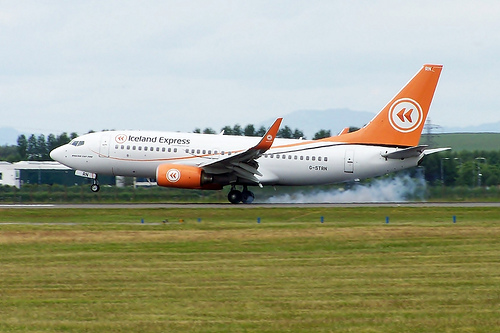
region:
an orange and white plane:
[51, 61, 448, 208]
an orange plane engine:
[155, 164, 211, 190]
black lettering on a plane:
[127, 132, 191, 146]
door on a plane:
[99, 134, 109, 157]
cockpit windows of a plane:
[67, 138, 84, 145]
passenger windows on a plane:
[111, 143, 330, 164]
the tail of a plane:
[360, 62, 442, 145]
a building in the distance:
[1, 155, 117, 192]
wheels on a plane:
[225, 188, 252, 203]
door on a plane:
[342, 146, 354, 175]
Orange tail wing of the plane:
[310, 64, 455, 148]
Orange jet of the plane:
[152, 164, 199, 186]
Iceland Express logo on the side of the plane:
[112, 130, 192, 147]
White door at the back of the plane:
[340, 149, 355, 175]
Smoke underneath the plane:
[260, 170, 426, 210]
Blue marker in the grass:
[448, 209, 464, 224]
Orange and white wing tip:
[258, 109, 285, 153]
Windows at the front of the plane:
[65, 139, 89, 147]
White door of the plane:
[97, 133, 111, 159]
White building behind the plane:
[0, 155, 138, 187]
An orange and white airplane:
[32, 52, 467, 204]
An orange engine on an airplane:
[146, 156, 214, 193]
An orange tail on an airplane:
[360, 48, 439, 150]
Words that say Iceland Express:
[124, 133, 197, 143]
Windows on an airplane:
[112, 145, 183, 152]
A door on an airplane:
[97, 131, 114, 161]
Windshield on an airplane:
[63, 133, 86, 150]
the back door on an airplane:
[343, 142, 360, 180]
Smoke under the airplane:
[259, 173, 445, 210]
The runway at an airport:
[14, 191, 494, 213]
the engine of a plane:
[155, 165, 217, 189]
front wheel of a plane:
[88, 181, 100, 193]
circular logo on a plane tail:
[387, 97, 422, 132]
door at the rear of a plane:
[340, 146, 356, 174]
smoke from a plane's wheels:
[250, 175, 427, 207]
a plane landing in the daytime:
[38, 53, 467, 210]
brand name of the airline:
[108, 129, 198, 146]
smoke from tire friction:
[240, 169, 429, 211]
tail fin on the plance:
[335, 58, 450, 142]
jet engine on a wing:
[151, 163, 232, 185]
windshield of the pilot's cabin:
[63, 136, 86, 149]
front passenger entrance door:
[95, 133, 109, 164]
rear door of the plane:
[341, 148, 362, 175]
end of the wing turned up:
[242, 113, 286, 158]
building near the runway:
[0, 159, 23, 196]